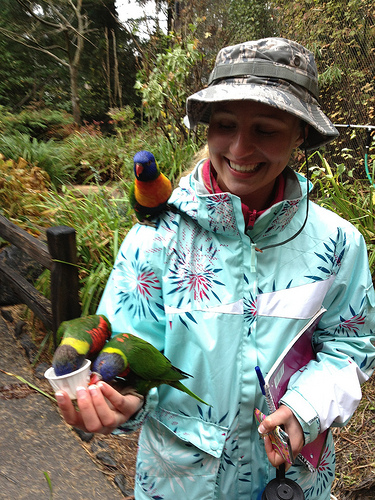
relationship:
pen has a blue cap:
[253, 365, 278, 423] [253, 365, 267, 394]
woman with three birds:
[55, 37, 372, 497] [52, 150, 213, 408]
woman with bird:
[55, 37, 372, 497] [129, 150, 174, 229]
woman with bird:
[55, 37, 372, 497] [51, 311, 112, 378]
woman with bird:
[55, 37, 372, 497] [89, 331, 211, 408]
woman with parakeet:
[55, 37, 372, 497] [129, 150, 174, 229]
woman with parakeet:
[55, 37, 372, 497] [51, 311, 112, 378]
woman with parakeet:
[55, 37, 372, 497] [89, 331, 211, 408]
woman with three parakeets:
[55, 37, 372, 497] [52, 150, 213, 408]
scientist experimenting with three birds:
[55, 37, 372, 497] [52, 150, 213, 408]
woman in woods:
[55, 37, 372, 497] [1, 4, 374, 196]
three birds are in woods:
[52, 150, 213, 408] [1, 4, 374, 196]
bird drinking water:
[51, 311, 112, 378] [43, 357, 92, 402]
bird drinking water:
[89, 331, 211, 408] [43, 357, 92, 402]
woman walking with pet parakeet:
[55, 37, 372, 497] [129, 150, 174, 229]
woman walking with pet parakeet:
[55, 37, 372, 497] [51, 311, 112, 378]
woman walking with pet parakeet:
[55, 37, 372, 497] [89, 331, 211, 408]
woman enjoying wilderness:
[55, 37, 372, 497] [1, 4, 374, 196]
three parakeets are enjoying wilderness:
[52, 150, 213, 408] [1, 4, 374, 196]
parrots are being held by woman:
[51, 313, 215, 414] [55, 37, 372, 497]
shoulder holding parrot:
[118, 201, 191, 239] [129, 150, 174, 229]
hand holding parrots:
[55, 381, 147, 436] [51, 313, 215, 414]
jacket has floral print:
[90, 157, 374, 499] [168, 242, 225, 307]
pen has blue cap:
[253, 365, 278, 423] [253, 365, 267, 394]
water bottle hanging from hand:
[264, 464, 306, 500] [258, 401, 304, 469]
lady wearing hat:
[55, 37, 372, 497] [180, 35, 341, 153]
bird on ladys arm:
[89, 331, 211, 408] [89, 209, 165, 396]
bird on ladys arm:
[51, 311, 112, 378] [89, 209, 165, 396]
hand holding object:
[55, 381, 147, 436] [43, 357, 92, 402]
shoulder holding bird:
[118, 201, 191, 239] [129, 150, 174, 229]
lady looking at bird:
[55, 37, 372, 497] [51, 311, 112, 378]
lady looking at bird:
[55, 37, 372, 497] [89, 331, 211, 408]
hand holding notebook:
[258, 401, 304, 469] [264, 307, 329, 473]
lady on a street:
[55, 37, 372, 497] [1, 312, 135, 498]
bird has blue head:
[129, 150, 174, 229] [132, 150, 161, 183]